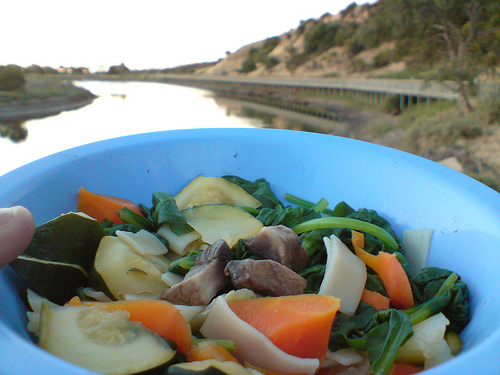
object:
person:
[0, 205, 39, 269]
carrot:
[218, 292, 344, 374]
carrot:
[75, 185, 145, 225]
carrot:
[82, 297, 197, 356]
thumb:
[0, 204, 38, 269]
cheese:
[314, 233, 371, 318]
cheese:
[198, 294, 337, 374]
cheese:
[114, 226, 171, 258]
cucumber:
[179, 200, 266, 250]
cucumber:
[33, 296, 179, 374]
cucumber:
[90, 234, 172, 300]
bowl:
[0, 126, 497, 373]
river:
[0, 74, 337, 177]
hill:
[191, 0, 499, 83]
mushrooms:
[160, 238, 234, 307]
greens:
[333, 200, 359, 217]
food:
[6, 254, 88, 312]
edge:
[86, 124, 377, 143]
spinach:
[294, 215, 400, 250]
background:
[0, 0, 500, 374]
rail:
[157, 68, 462, 112]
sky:
[0, 0, 380, 74]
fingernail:
[0, 206, 19, 227]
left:
[0, 0, 23, 374]